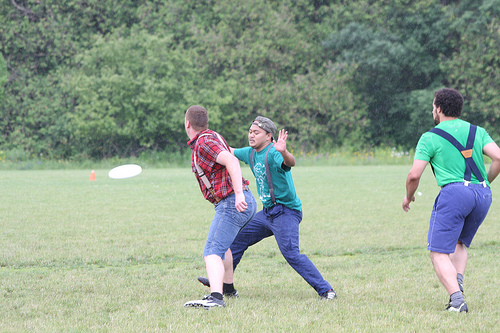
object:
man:
[183, 105, 259, 311]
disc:
[107, 164, 142, 180]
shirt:
[233, 145, 301, 210]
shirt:
[412, 119, 495, 187]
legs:
[200, 187, 257, 292]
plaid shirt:
[188, 128, 249, 201]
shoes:
[184, 294, 224, 308]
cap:
[251, 116, 278, 138]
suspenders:
[190, 133, 232, 202]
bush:
[0, 0, 500, 167]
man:
[196, 115, 339, 301]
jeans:
[225, 202, 333, 298]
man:
[402, 89, 499, 314]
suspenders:
[426, 123, 487, 187]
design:
[253, 163, 275, 205]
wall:
[162, 85, 248, 115]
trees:
[0, 0, 498, 163]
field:
[1, 158, 497, 333]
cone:
[89, 169, 96, 180]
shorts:
[424, 181, 493, 255]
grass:
[0, 202, 500, 333]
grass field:
[302, 172, 389, 266]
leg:
[228, 208, 273, 280]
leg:
[270, 215, 334, 293]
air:
[0, 0, 188, 222]